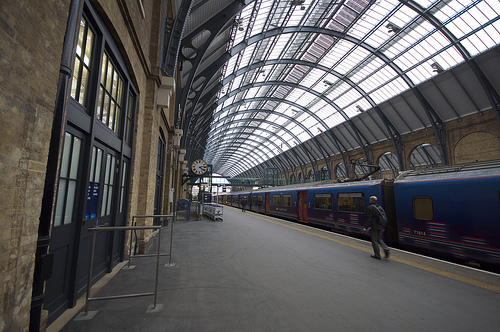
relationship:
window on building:
[335, 163, 347, 178] [1, 1, 497, 326]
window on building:
[321, 166, 329, 180] [1, 1, 497, 326]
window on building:
[51, 129, 84, 229] [132, 67, 156, 244]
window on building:
[355, 158, 370, 175] [1, 1, 497, 326]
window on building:
[299, 172, 305, 182] [1, 1, 497, 326]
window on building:
[283, 170, 293, 178] [1, 1, 497, 326]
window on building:
[52, 131, 83, 229] [5, 4, 183, 330]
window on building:
[329, 159, 371, 179] [98, 44, 153, 161]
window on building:
[94, 56, 129, 128] [20, 1, 328, 322]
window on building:
[94, 56, 129, 128] [1, 1, 497, 326]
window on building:
[408, 138, 448, 170] [0, 0, 242, 330]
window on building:
[373, 148, 402, 174] [0, 0, 242, 330]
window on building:
[355, 158, 370, 175] [0, 0, 242, 330]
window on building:
[334, 160, 348, 182] [0, 0, 242, 330]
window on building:
[321, 166, 329, 180] [0, 0, 242, 330]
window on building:
[297, 171, 303, 183] [1, 1, 497, 326]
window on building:
[86, 144, 106, 219] [1, 1, 497, 326]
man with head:
[366, 192, 389, 260] [367, 192, 377, 202]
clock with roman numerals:
[174, 147, 219, 179] [200, 159, 203, 163]